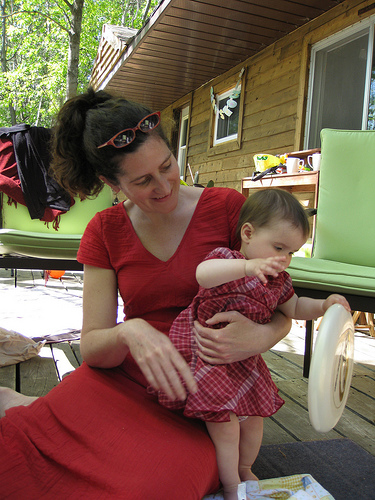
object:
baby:
[144, 187, 350, 500]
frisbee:
[307, 302, 355, 434]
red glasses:
[96, 110, 164, 148]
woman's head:
[83, 102, 181, 215]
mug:
[287, 157, 304, 175]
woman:
[2, 84, 246, 500]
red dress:
[0, 185, 248, 500]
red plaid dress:
[158, 245, 295, 424]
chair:
[286, 126, 374, 382]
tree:
[0, 1, 87, 124]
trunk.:
[65, 1, 83, 99]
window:
[212, 81, 242, 146]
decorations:
[209, 66, 247, 119]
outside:
[1, 0, 373, 500]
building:
[91, 2, 374, 244]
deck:
[1, 273, 373, 499]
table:
[238, 169, 320, 257]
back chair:
[0, 127, 112, 270]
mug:
[308, 154, 321, 173]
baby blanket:
[0, 124, 76, 231]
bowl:
[253, 153, 282, 175]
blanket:
[236, 472, 336, 499]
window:
[300, 15, 373, 161]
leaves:
[9, 22, 55, 87]